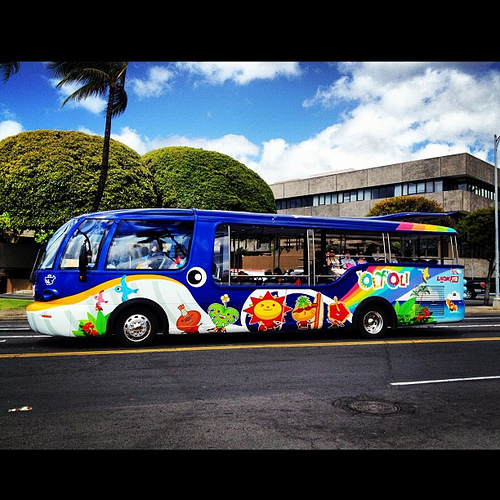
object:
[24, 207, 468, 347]
bus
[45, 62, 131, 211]
tree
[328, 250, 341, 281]
person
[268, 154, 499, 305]
building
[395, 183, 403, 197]
window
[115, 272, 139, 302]
bird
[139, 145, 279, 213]
tree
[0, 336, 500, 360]
line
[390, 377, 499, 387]
line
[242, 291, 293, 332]
sun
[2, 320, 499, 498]
street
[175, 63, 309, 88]
cloud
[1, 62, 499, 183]
sky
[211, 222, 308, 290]
window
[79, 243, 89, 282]
mirror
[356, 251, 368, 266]
passenger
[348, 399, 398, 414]
manhole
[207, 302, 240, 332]
heart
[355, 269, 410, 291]
word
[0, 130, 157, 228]
bush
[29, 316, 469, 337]
bottom